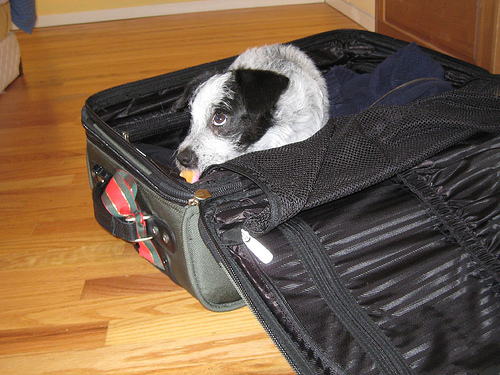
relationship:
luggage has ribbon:
[82, 26, 499, 374] [98, 165, 170, 269]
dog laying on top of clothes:
[166, 37, 330, 196] [325, 43, 452, 112]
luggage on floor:
[82, 26, 499, 374] [2, 2, 368, 373]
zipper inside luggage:
[119, 128, 133, 142] [82, 26, 499, 374]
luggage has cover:
[82, 26, 499, 374] [198, 71, 499, 374]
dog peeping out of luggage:
[166, 37, 330, 196] [82, 26, 499, 374]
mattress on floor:
[2, 0, 26, 101] [2, 2, 368, 373]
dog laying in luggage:
[166, 37, 330, 196] [82, 26, 499, 374]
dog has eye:
[166, 37, 330, 196] [208, 110, 227, 130]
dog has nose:
[166, 37, 330, 196] [176, 149, 198, 171]